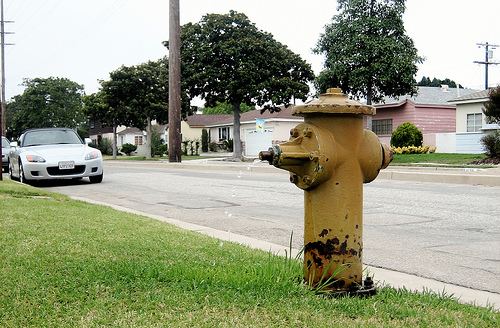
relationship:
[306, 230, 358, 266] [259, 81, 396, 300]
rust on fire hydrant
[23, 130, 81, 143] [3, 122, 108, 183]
windshield of sports car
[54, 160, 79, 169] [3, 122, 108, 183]
license plate on sports car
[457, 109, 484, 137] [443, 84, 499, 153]
window in house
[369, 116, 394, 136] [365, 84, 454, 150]
window in house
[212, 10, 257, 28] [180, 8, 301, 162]
top of tree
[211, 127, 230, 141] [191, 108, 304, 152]
window in house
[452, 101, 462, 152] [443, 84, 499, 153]
corner of house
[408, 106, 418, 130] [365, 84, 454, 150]
corner of house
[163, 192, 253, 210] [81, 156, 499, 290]
asphalt on street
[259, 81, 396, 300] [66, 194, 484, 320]
fire hydrant next to curb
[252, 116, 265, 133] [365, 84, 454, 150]
flag on side of house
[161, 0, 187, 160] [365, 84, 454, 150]
pole behind house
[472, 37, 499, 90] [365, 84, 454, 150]
pole behind house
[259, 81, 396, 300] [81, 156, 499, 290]
fire hydrant next to street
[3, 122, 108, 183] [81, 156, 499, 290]
sports car on street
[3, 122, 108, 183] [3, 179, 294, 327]
sports car next to grass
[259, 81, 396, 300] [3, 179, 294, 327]
fire hydrant in grass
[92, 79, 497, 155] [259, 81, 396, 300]
houses behind fire hydrant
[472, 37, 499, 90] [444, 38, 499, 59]
pole holding power lines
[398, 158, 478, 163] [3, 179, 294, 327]
edge of grass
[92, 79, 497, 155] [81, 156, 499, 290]
houses next to street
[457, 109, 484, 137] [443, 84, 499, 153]
window from house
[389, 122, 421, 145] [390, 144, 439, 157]
bush with flowers